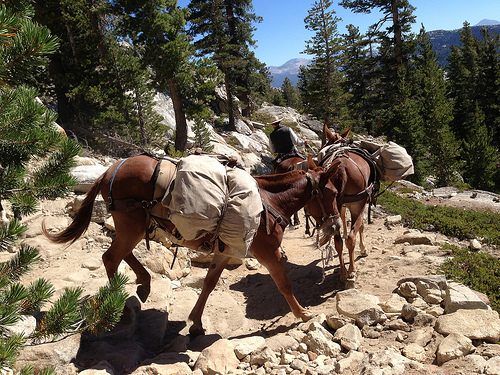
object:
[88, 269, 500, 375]
rocks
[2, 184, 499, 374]
trail side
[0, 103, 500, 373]
terrain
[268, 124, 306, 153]
shirt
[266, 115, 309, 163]
man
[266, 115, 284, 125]
hat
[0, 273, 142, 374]
needles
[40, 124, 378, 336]
horse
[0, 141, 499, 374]
mountain path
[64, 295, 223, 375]
shadow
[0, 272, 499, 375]
ground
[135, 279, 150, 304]
foot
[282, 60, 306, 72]
sunshine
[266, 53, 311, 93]
mountain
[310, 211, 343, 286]
reins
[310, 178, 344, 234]
face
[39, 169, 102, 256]
tail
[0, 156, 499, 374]
trail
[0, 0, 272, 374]
tree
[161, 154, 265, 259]
bag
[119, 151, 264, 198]
back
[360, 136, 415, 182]
bag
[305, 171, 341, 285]
harness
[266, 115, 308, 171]
arm rides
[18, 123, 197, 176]
ground